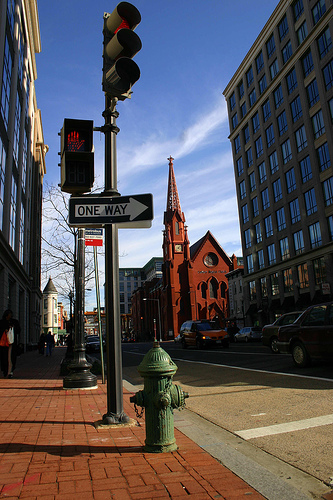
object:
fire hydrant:
[130, 340, 189, 454]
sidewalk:
[0, 345, 269, 499]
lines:
[232, 340, 332, 490]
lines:
[122, 342, 331, 444]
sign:
[67, 193, 152, 229]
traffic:
[178, 302, 333, 367]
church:
[130, 154, 243, 343]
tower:
[161, 154, 196, 340]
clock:
[175, 244, 183, 251]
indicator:
[58, 117, 95, 191]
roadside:
[73, 343, 289, 499]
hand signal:
[67, 131, 85, 152]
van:
[179, 319, 231, 350]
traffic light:
[101, 1, 142, 426]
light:
[106, 1, 140, 35]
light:
[105, 27, 141, 60]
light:
[106, 56, 141, 92]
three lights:
[102, 0, 141, 98]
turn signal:
[202, 336, 206, 339]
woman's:
[0, 310, 22, 379]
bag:
[6, 327, 14, 345]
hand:
[5, 329, 8, 332]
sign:
[83, 228, 102, 247]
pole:
[103, 95, 132, 425]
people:
[45, 331, 55, 357]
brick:
[63, 430, 86, 442]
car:
[274, 303, 333, 367]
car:
[260, 312, 301, 354]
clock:
[165, 246, 168, 256]